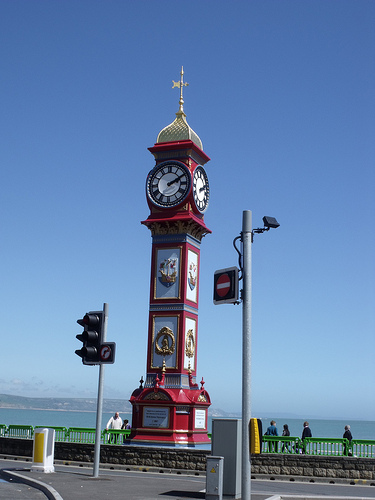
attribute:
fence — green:
[261, 433, 374, 460]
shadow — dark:
[154, 478, 218, 497]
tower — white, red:
[116, 76, 212, 365]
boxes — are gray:
[207, 402, 250, 496]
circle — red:
[215, 273, 230, 295]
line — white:
[215, 282, 233, 292]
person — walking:
[340, 422, 356, 459]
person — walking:
[301, 417, 313, 449]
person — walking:
[278, 419, 291, 448]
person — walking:
[264, 417, 277, 452]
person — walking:
[106, 410, 123, 440]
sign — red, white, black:
[210, 269, 241, 306]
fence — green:
[1, 422, 374, 461]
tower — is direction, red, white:
[126, 59, 216, 452]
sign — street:
[94, 338, 119, 359]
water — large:
[3, 409, 95, 424]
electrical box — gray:
[210, 414, 242, 498]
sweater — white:
[107, 415, 124, 432]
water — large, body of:
[0, 406, 373, 453]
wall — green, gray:
[2, 436, 374, 482]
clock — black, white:
[149, 161, 188, 206]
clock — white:
[143, 159, 192, 209]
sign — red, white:
[210, 266, 242, 301]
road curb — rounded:
[251, 474, 374, 488]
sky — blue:
[3, 3, 372, 419]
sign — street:
[212, 266, 238, 303]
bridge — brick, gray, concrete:
[75, 392, 251, 488]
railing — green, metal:
[1, 421, 366, 457]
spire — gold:
[155, 67, 204, 157]